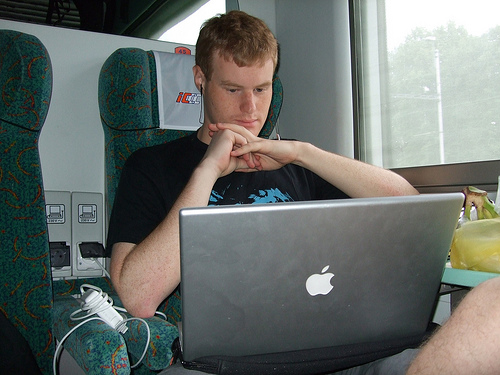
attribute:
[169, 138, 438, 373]
cover — for apple lap top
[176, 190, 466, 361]
laptop — silver, gray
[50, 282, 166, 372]
cord — gray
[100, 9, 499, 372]
man — sitting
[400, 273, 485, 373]
leg — hairy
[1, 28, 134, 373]
seat — green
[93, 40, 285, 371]
seat — green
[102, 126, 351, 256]
shirt — black, blue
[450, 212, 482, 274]
container — yellow